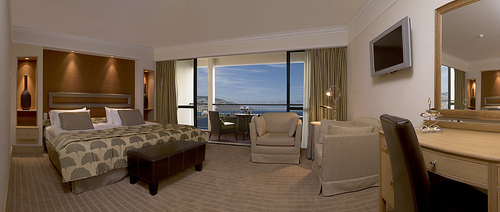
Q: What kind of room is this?
A: Hotel.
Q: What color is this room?
A: Tan.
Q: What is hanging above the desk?
A: Mirror.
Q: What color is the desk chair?
A: Brown.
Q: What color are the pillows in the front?
A: Brown.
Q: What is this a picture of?
A: Bedroom.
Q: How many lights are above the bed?
A: Two.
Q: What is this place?
A: A hotel.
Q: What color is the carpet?
A: Taupe.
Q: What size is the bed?
A: King size.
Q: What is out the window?
A: The ocean.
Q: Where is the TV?
A: On the wall next to the vanity.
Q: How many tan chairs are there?
A: Two.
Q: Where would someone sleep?
A: In the bed.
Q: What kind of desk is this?
A: Wooden.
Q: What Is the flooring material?
A: Carpeting.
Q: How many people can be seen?
A: Zero.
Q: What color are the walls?
A: White.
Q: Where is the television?
A: On the right hand side wall.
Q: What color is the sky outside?
A: Blue.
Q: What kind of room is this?
A: A luxury hotel room.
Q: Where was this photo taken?
A: In a hotel.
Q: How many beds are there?
A: One.